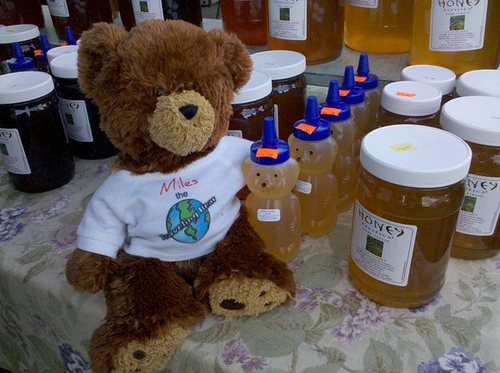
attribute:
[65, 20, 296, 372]
bear — hot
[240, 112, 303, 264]
plastic bottle — shaped like bears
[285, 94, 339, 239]
plastic bottle — shaped like bears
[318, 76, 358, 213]
plastic bottle — shaped like bears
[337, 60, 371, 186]
plastic bottle — shaped like bears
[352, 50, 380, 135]
plastic bottle — shaped like bears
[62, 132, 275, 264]
shirt — white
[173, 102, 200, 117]
nose — black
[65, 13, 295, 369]
teddy bear — brown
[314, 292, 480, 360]
table cloth — flowered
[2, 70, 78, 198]
honey — fresh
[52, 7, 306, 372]
teddy bear — brown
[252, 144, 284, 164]
tag — orange, sticker, price tag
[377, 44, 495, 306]
jars — honey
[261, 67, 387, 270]
bottles — bear-shaped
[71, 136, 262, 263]
shirt — white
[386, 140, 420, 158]
sticker — orange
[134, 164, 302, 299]
shirt — white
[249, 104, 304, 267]
bottle — teddy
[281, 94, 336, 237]
bottle — teddy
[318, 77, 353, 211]
bottle — teddy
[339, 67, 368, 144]
bottle — teddy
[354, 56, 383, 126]
bottle — teddy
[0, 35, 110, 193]
honey — dark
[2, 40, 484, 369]
table cloth — green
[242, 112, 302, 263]
bottle — bear-shaped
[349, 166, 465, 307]
honey — fresh